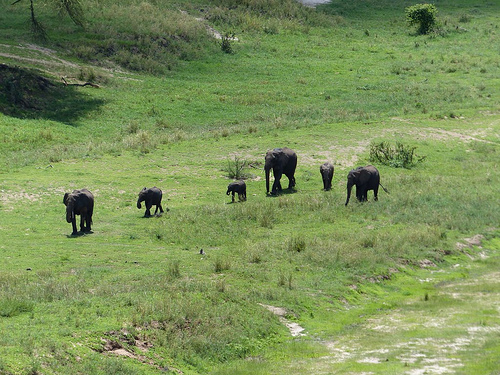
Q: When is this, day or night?
A: Day time.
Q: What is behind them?
A: Mountains.